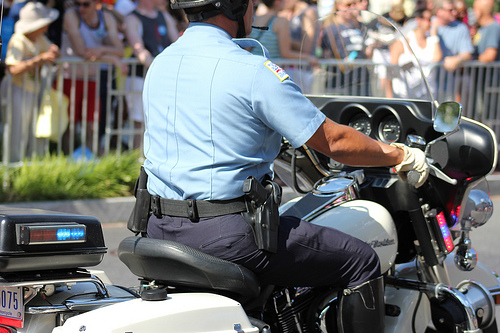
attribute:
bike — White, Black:
[301, 159, 478, 314]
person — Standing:
[9, 7, 105, 209]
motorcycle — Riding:
[296, 7, 498, 309]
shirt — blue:
[130, 29, 325, 202]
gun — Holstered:
[234, 150, 290, 279]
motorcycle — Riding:
[1, 8, 498, 329]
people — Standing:
[24, 8, 499, 117]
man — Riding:
[133, 0, 382, 327]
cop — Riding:
[160, 0, 398, 328]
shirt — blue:
[117, 23, 292, 191]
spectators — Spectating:
[1, 0, 499, 160]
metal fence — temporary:
[0, 53, 498, 197]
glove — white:
[384, 140, 426, 175]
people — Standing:
[318, 4, 478, 56]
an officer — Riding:
[130, 22, 420, 293]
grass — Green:
[3, 150, 145, 203]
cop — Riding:
[133, 1, 441, 332]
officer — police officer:
[133, 2, 329, 266]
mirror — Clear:
[425, 99, 467, 131]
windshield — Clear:
[300, 15, 468, 161]